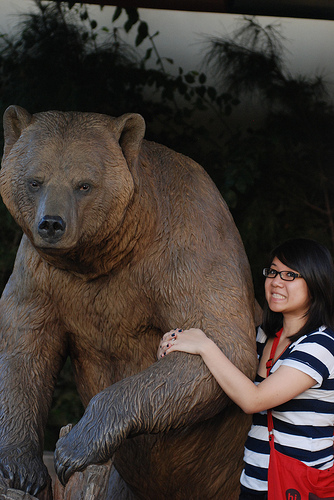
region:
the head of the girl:
[262, 244, 321, 316]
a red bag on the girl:
[266, 441, 333, 498]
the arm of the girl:
[205, 327, 332, 415]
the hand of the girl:
[162, 322, 214, 359]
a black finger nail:
[170, 331, 178, 338]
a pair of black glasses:
[261, 264, 311, 281]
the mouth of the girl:
[267, 288, 287, 302]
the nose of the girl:
[268, 272, 286, 289]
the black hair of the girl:
[274, 234, 333, 328]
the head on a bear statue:
[0, 101, 152, 254]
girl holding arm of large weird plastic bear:
[25, 104, 312, 439]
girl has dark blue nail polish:
[138, 308, 237, 374]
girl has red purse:
[256, 348, 332, 494]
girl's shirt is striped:
[291, 397, 325, 453]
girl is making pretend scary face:
[247, 251, 319, 333]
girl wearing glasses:
[261, 268, 309, 288]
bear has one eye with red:
[17, 170, 104, 202]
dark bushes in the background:
[39, 8, 306, 152]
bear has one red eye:
[74, 177, 97, 195]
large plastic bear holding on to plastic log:
[15, 345, 194, 492]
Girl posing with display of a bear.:
[9, 91, 332, 480]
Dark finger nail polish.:
[148, 322, 216, 355]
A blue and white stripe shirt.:
[238, 311, 332, 488]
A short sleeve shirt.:
[240, 322, 333, 492]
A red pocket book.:
[262, 322, 329, 497]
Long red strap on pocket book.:
[264, 325, 290, 461]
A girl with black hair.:
[157, 223, 333, 449]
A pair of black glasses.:
[251, 251, 315, 287]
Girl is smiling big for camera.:
[248, 224, 332, 338]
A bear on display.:
[2, 90, 244, 488]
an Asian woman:
[163, 193, 330, 498]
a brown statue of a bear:
[2, 97, 253, 499]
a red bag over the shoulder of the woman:
[239, 310, 329, 497]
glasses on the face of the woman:
[250, 247, 333, 331]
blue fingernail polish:
[146, 317, 196, 364]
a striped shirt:
[234, 316, 323, 497]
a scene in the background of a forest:
[10, 7, 318, 238]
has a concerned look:
[225, 219, 333, 328]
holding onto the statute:
[151, 274, 277, 443]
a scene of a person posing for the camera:
[1, 3, 331, 498]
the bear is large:
[2, 107, 260, 497]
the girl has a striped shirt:
[239, 323, 332, 495]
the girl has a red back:
[268, 327, 331, 497]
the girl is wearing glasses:
[258, 268, 304, 282]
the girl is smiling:
[266, 291, 286, 301]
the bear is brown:
[2, 110, 235, 496]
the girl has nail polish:
[157, 323, 181, 360]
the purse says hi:
[285, 489, 300, 498]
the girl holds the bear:
[159, 326, 256, 428]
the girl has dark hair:
[261, 248, 331, 338]